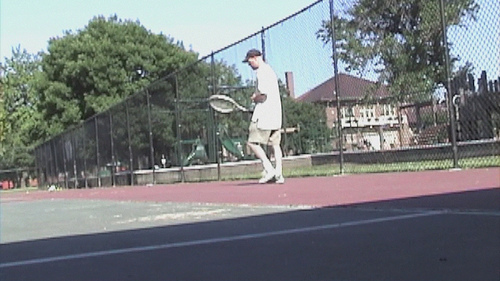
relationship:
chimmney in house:
[284, 70, 295, 98] [261, 33, 454, 176]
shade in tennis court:
[82, 229, 369, 279] [40, 102, 406, 259]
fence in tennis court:
[22, 6, 499, 191] [4, 186, 498, 279]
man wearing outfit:
[240, 49, 296, 185] [245, 71, 286, 163]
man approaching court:
[240, 49, 296, 185] [0, 166, 499, 278]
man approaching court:
[240, 49, 296, 185] [1, 189, 483, 271]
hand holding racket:
[246, 93, 264, 112] [208, 95, 256, 114]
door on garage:
[381, 123, 399, 147] [381, 127, 406, 153]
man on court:
[240, 49, 296, 185] [4, 182, 491, 279]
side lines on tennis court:
[74, 186, 457, 209] [4, 186, 498, 279]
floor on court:
[21, 183, 323, 265] [0, 162, 500, 280]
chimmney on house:
[281, 71, 298, 102] [281, 68, 416, 153]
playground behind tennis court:
[169, 64, 497, 169] [0, 159, 500, 279]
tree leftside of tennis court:
[313, 1, 498, 181] [1, 142, 499, 279]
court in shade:
[0, 162, 500, 280] [9, 185, 494, 275]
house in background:
[276, 60, 444, 164] [12, 9, 479, 175]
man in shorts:
[240, 49, 296, 185] [209, 121, 303, 159]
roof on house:
[295, 55, 408, 106] [294, 62, 417, 122]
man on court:
[181, 40, 305, 167] [0, 162, 500, 280]